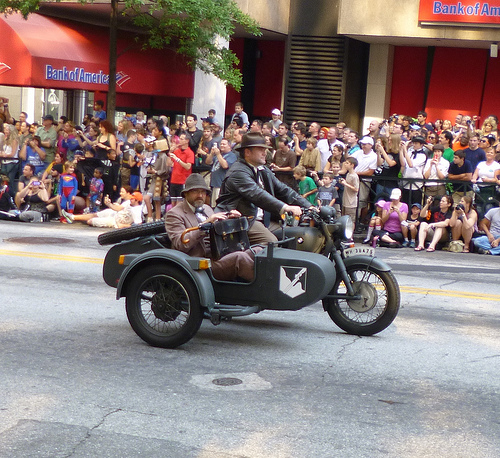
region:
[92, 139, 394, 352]
two men riding a motorcycle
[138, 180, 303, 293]
a man sitting in a side cart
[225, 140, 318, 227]
the man driving the motorcycle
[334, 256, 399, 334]
the front tire of the motorcycle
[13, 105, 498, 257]
people standing on the street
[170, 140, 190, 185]
a man wearing a red shirt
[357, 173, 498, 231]
a black fence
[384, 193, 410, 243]
a person sitting on the ground wearing a purple shirt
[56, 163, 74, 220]
a child in a superman outfit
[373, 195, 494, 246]
people sitting on the ground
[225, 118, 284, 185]
man is wearing a fedora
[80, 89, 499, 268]
the peaople are watching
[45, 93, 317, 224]
the peaople are watching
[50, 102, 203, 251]
the peaople are watching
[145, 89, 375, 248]
the peaople are watching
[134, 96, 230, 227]
the peaople are watching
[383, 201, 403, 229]
the tshirt is purple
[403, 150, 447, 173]
the shirt is white in color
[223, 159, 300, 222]
the jacket is black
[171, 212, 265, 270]
the suit is brown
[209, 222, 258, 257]
the bag is black in color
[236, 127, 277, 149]
the hat is brown in color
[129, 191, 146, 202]
the hat is orange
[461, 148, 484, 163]
the shirt is blue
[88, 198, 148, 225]
the man has his legs streched on the road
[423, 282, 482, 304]
two lines are on the road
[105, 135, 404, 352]
A man driving his motor cycle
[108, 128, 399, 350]
A beautiful motorcycle with sidecar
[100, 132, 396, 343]
A man sitting in the side car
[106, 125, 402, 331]
A ride pillion holding his baggage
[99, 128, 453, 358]
An extra wheel is fixed on the back side of the side car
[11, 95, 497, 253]
Group of people waiting to watch an event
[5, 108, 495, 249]
Bunch of people sitting besides the road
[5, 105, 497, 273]
People are holding camera to take a snap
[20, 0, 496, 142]
A sign board displaying the name of a bank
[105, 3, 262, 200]
A tall tree stands in front of the bank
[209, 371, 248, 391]
a metal drain cover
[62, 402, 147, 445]
a crack in the asphalt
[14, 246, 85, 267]
a bright yellow median line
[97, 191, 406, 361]
an old style motorcycle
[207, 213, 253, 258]
an old black briefcase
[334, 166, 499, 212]
a black metal fence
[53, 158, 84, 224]
a boy in a superman costume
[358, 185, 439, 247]
a family sitting on the curb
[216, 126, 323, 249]
a man in a leather jacket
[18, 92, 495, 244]
a large group of bystanders